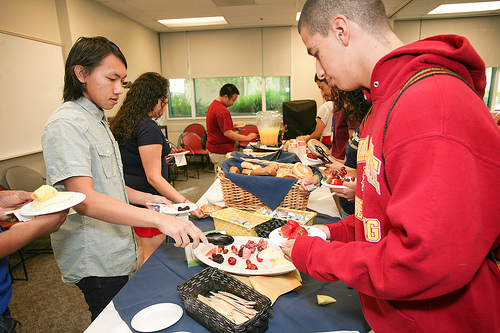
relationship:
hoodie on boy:
[291, 34, 500, 333] [46, 34, 136, 291]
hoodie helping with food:
[291, 34, 500, 333] [195, 221, 276, 277]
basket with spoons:
[216, 152, 308, 217] [196, 288, 251, 327]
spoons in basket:
[196, 288, 251, 327] [216, 152, 308, 217]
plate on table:
[193, 236, 298, 277] [143, 195, 296, 330]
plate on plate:
[193, 236, 298, 277] [192, 232, 292, 271]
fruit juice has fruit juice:
[256, 128, 277, 146] [256, 128, 277, 146]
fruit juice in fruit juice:
[256, 128, 277, 146] [256, 128, 277, 146]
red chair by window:
[182, 130, 212, 175] [165, 73, 291, 120]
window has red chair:
[165, 73, 291, 120] [182, 130, 212, 175]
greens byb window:
[175, 91, 283, 112] [165, 73, 291, 120]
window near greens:
[165, 73, 291, 120] [175, 91, 283, 112]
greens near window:
[175, 91, 283, 112] [165, 73, 291, 120]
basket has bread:
[216, 156, 311, 212] [224, 155, 314, 180]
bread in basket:
[224, 155, 314, 180] [216, 156, 311, 212]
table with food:
[138, 271, 183, 330] [202, 240, 291, 270]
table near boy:
[138, 271, 183, 330] [40, 29, 177, 309]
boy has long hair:
[39, 35, 204, 317] [60, 33, 127, 101]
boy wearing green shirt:
[39, 35, 204, 317] [39, 95, 146, 282]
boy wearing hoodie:
[262, 0, 498, 331] [291, 34, 498, 331]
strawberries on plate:
[280, 219, 309, 236] [271, 225, 328, 245]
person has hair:
[111, 72, 212, 222] [118, 72, 165, 134]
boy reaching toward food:
[279, 0, 500, 331] [189, 140, 414, 331]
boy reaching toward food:
[39, 35, 208, 323] [189, 140, 414, 331]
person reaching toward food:
[111, 72, 204, 215] [189, 140, 414, 331]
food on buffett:
[189, 140, 414, 331] [164, 130, 368, 300]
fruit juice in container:
[256, 128, 277, 146] [251, 102, 286, 152]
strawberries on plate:
[280, 219, 308, 240] [258, 216, 336, 262]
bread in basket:
[228, 161, 314, 179] [218, 154, 309, 211]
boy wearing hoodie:
[279, 0, 500, 331] [291, 34, 498, 331]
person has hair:
[111, 72, 212, 222] [121, 73, 169, 138]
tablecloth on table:
[110, 209, 365, 331] [82, 143, 370, 331]